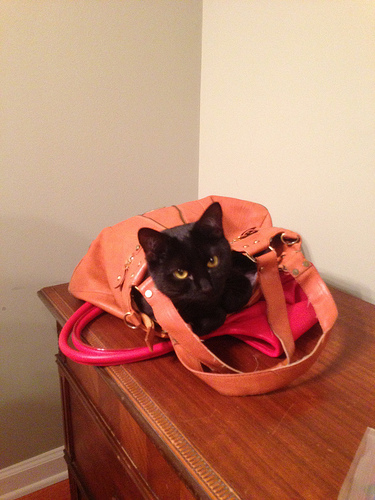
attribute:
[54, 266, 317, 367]
purse — bright pink